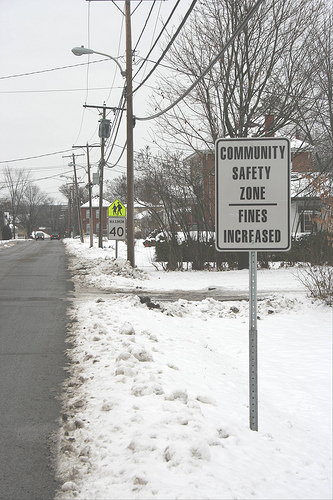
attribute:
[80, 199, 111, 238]
house — red, brick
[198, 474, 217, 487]
snow — white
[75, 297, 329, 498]
snow patch — white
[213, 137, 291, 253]
sign — road sign, white, black, street sign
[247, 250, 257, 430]
pole — metallic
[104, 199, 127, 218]
sign — bright yellow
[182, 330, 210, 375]
snow — white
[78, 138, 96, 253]
telephone pole — wooden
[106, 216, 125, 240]
sign — black, white, road sign, street sign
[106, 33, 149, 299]
pole — wooden, telephone pole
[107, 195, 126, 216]
sign — children crossing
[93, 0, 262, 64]
power lines — above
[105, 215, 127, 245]
sign — speed limit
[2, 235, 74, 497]
road — black, asphalt, wet, shiny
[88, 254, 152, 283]
snow pile — dirty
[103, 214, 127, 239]
sign — street sign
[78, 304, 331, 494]
snow — white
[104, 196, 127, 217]
sign — yellow, black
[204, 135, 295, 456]
pole — metallic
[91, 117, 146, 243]
pole — telephone pole, wooden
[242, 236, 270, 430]
post — metal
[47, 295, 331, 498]
snow — white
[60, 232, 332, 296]
snow — white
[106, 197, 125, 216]
sign — street sign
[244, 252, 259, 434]
pole — metallic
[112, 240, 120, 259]
pole — metallic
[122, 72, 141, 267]
pole — metallic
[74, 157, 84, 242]
pole — metallic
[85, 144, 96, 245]
pole — metallic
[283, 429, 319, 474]
snow patch — white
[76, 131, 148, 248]
pole — wooden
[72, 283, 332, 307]
driveway — shoveled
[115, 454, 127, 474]
snow — white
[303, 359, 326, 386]
snow — white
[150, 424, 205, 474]
snow — white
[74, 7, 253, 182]
wires — many